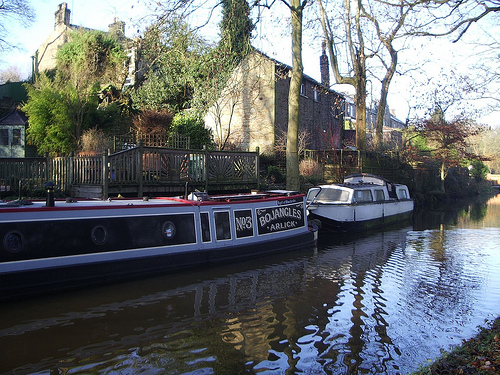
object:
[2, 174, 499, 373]
water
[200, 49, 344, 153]
house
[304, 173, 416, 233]
boat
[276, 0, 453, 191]
trees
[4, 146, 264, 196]
fence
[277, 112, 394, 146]
ground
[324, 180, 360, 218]
ground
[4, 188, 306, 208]
dock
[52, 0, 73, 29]
chimney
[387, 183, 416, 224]
back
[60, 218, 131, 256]
circular window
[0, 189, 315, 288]
front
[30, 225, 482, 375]
river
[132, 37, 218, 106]
leaves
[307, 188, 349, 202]
windshield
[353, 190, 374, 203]
window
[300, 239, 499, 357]
light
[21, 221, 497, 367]
surface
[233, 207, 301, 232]
name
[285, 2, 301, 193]
tree trunk